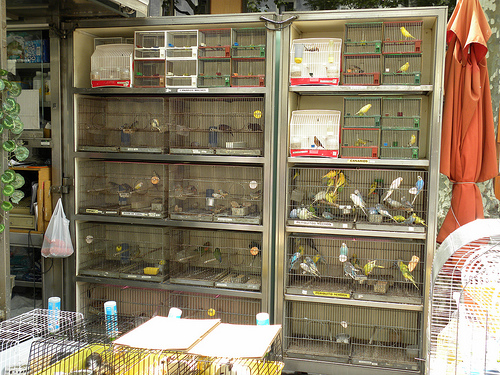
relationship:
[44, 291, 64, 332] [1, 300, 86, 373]
water bottle on side of cage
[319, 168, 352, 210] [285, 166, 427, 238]
multiple birds in crate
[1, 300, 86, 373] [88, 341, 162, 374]
cage has yellow bottom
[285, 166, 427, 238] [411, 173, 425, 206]
cage has blue bird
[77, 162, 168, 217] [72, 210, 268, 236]
cage on top of shelf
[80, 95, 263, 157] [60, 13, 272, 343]
cages inside of unit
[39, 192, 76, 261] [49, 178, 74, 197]
bag hanging from hook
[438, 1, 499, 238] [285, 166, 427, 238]
umbrella to right of crate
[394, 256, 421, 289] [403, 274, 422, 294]
bird has long tail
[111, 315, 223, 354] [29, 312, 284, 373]
folder on top of cages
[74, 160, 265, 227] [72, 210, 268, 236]
two cages on top of shelf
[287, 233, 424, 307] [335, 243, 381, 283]
crate has multiple birds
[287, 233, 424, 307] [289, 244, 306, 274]
crate has colorful bird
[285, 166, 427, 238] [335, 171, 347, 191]
crate has yellow bird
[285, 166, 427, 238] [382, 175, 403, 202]
crate has white bird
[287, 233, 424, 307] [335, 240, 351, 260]
crate has blue bird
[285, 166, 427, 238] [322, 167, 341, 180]
crate has yellow bird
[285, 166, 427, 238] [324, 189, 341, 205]
crate has yellow bird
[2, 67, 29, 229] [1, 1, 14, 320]
vine on pole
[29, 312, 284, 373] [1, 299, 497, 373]
three cages are at bottom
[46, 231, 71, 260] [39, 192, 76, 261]
red bag inside of white bag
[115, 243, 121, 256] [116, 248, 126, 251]
bird has yellow breast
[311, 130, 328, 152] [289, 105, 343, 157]
brown bird inside of white cage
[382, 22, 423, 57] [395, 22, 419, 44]
crate has one bird